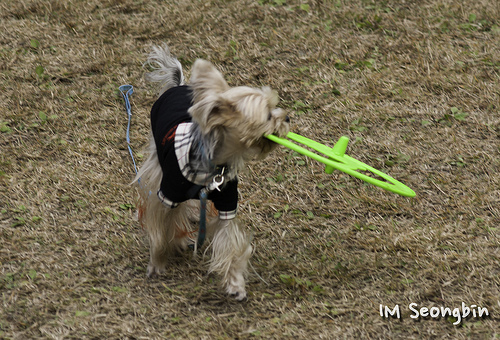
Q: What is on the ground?
A: Dried grass.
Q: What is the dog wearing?
A: A sweater.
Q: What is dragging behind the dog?
A: A blue leash.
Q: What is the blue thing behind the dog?
A: A leash.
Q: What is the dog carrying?
A: Flying toy.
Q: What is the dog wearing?
A: Sweater.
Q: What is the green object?
A: Flying toy.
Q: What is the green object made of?
A: Plastic.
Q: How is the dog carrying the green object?
A: His teet.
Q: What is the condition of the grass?
A: Dead.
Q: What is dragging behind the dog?
A: Leash.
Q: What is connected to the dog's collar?
A: Leash.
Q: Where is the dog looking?
A: Right.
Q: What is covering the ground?
A: Dead grass.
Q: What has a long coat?
A: The dog.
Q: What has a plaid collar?
A: The black shirt.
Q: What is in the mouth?
A: The green plastic toy.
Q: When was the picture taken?
A: Daytime.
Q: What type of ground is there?
A: Grass.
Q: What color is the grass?
A: Brown.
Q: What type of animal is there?
A: A dog.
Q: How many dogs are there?
A: One.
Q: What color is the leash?
A: Blue.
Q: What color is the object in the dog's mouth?
A: Green.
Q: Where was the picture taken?
A: In a yard.